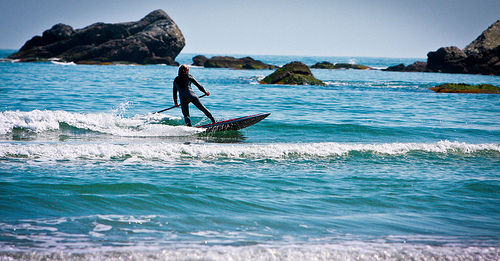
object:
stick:
[149, 90, 211, 117]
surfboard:
[200, 105, 270, 133]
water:
[254, 82, 441, 254]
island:
[250, 57, 436, 86]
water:
[298, 147, 427, 214]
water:
[1, 49, 494, 259]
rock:
[8, 9, 186, 66]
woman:
[162, 66, 222, 126]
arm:
[189, 75, 210, 95]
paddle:
[197, 93, 207, 98]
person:
[167, 58, 216, 129]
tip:
[255, 111, 272, 119]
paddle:
[152, 93, 209, 117]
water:
[114, 83, 372, 190]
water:
[100, 68, 330, 178]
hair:
[173, 60, 194, 78]